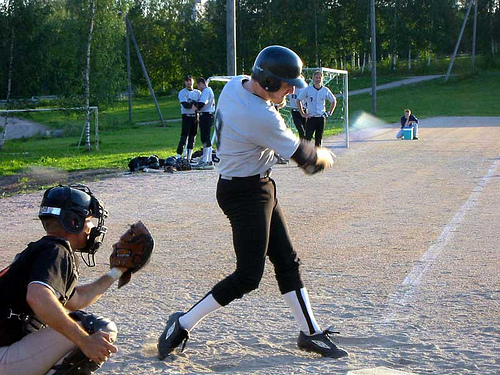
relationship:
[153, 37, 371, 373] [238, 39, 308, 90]
man wearing helmet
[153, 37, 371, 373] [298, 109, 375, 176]
man swinging bat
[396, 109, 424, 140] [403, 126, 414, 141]
man behind pitcher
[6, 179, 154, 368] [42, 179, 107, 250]
man wearing helmet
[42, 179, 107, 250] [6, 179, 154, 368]
helmet for man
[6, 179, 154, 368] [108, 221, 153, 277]
man wearing mitt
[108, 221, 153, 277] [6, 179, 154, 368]
mitt of man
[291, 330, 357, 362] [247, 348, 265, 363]
cleet in dirt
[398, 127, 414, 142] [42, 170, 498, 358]
pitcher on ground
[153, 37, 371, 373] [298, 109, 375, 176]
player swinging bat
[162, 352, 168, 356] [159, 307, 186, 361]
toe in shoe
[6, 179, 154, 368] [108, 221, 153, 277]
catcher with mitt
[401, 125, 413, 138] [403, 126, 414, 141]
person behind pitcher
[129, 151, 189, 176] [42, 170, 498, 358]
bags on ground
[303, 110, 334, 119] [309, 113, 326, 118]
hands on hips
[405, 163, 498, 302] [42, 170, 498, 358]
line on ground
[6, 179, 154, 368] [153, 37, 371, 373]
catcher behind hitter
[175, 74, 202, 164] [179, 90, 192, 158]
man in uniform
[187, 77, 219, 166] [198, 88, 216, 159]
player in uniform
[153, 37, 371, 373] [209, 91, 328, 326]
player in uniform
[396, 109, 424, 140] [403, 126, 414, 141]
man with pitcher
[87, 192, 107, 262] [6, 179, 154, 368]
face guard of catcher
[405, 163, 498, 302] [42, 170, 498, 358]
line into ground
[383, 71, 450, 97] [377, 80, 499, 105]
trail in grass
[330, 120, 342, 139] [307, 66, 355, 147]
net in goal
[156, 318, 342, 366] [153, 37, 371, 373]
shoes of player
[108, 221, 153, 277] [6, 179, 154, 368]
mitt of catcher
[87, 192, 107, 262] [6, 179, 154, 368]
mask of catcher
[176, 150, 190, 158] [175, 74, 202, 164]
socks of man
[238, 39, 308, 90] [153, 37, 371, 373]
helmet of player